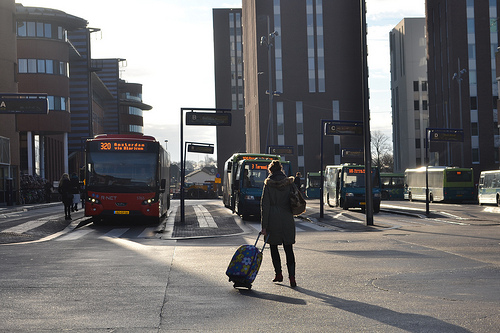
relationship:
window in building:
[327, 96, 344, 121] [238, 1, 375, 196]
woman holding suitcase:
[252, 157, 322, 286] [217, 239, 268, 290]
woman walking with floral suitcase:
[259, 160, 299, 288] [221, 223, 274, 292]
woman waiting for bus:
[259, 160, 299, 288] [82, 131, 169, 228]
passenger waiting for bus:
[59, 172, 74, 219] [82, 131, 169, 228]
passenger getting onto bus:
[58, 172, 75, 221] [82, 131, 169, 228]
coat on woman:
[254, 163, 305, 253] [266, 159, 335, 274]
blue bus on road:
[318, 156, 385, 213] [0, 199, 500, 330]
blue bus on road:
[237, 157, 276, 216] [0, 199, 500, 330]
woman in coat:
[259, 160, 299, 288] [260, 170, 304, 246]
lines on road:
[185, 200, 226, 236] [0, 199, 500, 330]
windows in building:
[21, 16, 81, 41] [20, 0, 95, 164]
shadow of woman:
[298, 291, 465, 329] [259, 160, 299, 288]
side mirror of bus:
[154, 175, 169, 198] [82, 131, 169, 228]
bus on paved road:
[78, 132, 170, 226] [61, 254, 438, 324]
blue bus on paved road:
[233, 159, 292, 219] [61, 254, 438, 324]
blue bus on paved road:
[322, 162, 382, 214] [61, 254, 438, 324]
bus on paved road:
[402, 165, 478, 203] [61, 254, 438, 324]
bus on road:
[82, 131, 169, 228] [4, 198, 497, 332]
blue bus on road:
[322, 162, 382, 214] [4, 198, 497, 332]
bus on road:
[402, 165, 478, 203] [4, 198, 497, 332]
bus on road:
[430, 164, 475, 204] [4, 198, 497, 332]